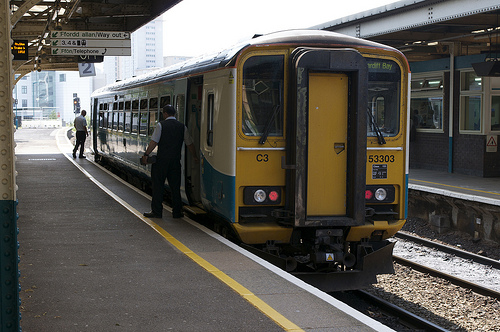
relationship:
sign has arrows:
[48, 24, 131, 55] [51, 31, 59, 59]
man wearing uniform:
[149, 103, 187, 225] [148, 119, 185, 222]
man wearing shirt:
[149, 103, 187, 225] [155, 118, 188, 147]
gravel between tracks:
[416, 279, 458, 305] [385, 300, 429, 329]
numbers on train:
[365, 146, 395, 162] [232, 30, 406, 239]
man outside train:
[149, 103, 187, 225] [232, 30, 406, 239]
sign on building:
[48, 24, 131, 55] [0, 59, 15, 300]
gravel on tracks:
[416, 279, 448, 300] [385, 300, 429, 329]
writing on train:
[252, 152, 271, 162] [232, 30, 406, 239]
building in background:
[23, 76, 58, 111] [27, 79, 57, 118]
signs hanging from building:
[48, 24, 131, 55] [0, 59, 15, 300]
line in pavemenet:
[179, 239, 217, 279] [118, 277, 190, 323]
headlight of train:
[251, 185, 266, 207] [232, 30, 406, 239]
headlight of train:
[376, 188, 389, 204] [232, 30, 406, 239]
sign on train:
[252, 152, 271, 162] [232, 30, 406, 239]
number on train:
[365, 146, 395, 162] [232, 30, 406, 239]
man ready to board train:
[74, 109, 90, 153] [232, 30, 406, 239]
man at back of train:
[149, 103, 187, 225] [232, 30, 406, 239]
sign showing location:
[48, 24, 131, 55] [66, 46, 104, 58]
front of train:
[236, 37, 407, 255] [232, 30, 406, 239]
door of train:
[188, 79, 205, 205] [232, 30, 406, 239]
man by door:
[149, 103, 187, 225] [188, 79, 205, 205]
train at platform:
[232, 30, 406, 239] [11, 3, 496, 331]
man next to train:
[149, 103, 187, 225] [232, 30, 406, 239]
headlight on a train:
[251, 185, 266, 207] [232, 30, 406, 239]